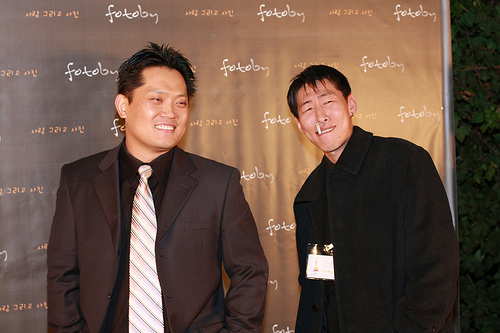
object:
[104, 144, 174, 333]
shirt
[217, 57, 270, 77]
lettering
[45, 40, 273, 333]
man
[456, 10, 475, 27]
tree leaves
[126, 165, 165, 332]
tie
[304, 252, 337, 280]
card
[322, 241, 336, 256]
clip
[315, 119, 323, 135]
cigarette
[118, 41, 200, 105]
hair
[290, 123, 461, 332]
coat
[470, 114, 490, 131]
leaves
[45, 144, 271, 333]
jacket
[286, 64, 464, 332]
man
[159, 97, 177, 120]
nose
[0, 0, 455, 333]
backdrop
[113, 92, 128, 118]
ear